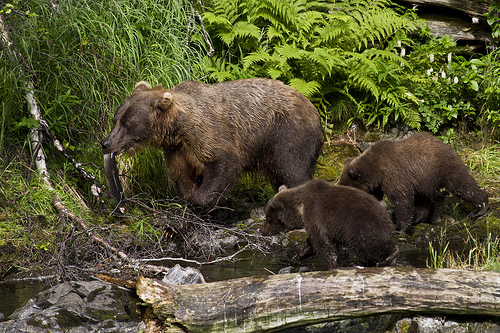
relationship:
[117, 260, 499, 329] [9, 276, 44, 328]
log by water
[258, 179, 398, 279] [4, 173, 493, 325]
bear sitting on ground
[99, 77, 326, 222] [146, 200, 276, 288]
bear facing ground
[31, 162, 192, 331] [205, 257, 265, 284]
branch across river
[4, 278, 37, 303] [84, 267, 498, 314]
water near logs